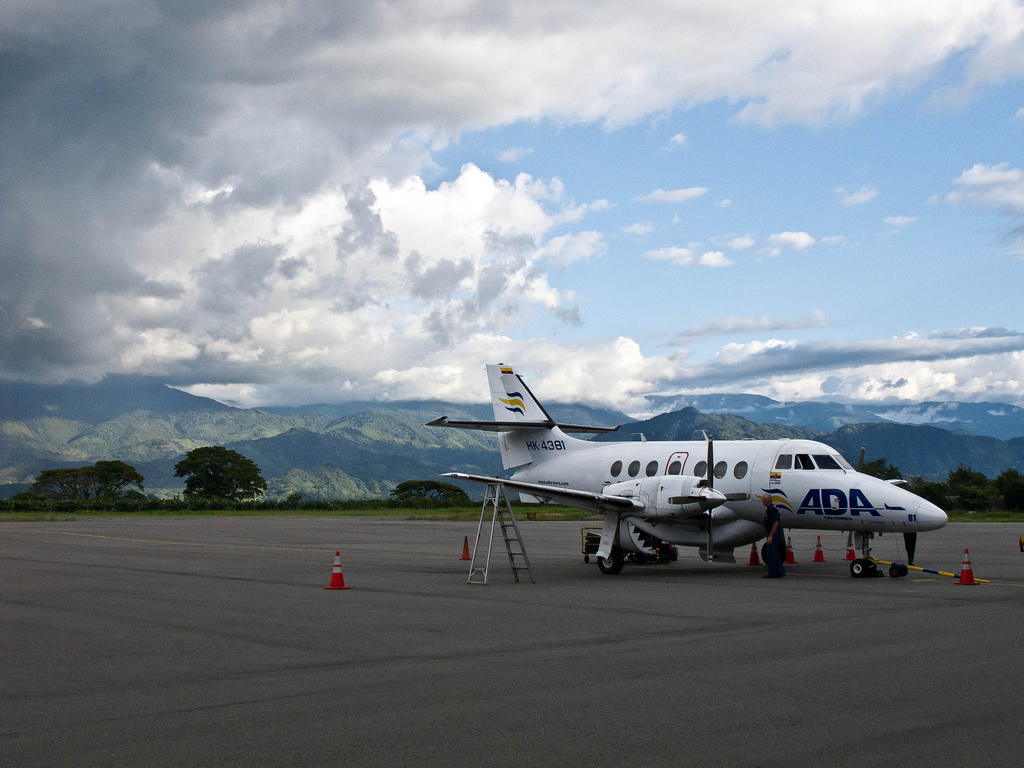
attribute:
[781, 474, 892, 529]
letters — blue 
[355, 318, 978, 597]
plane — white 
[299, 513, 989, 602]
cones — orange 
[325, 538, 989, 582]
stripes — white 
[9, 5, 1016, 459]
sky — blue 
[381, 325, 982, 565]
plane — small , white 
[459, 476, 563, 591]
ladder — silver  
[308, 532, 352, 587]
cone — orange 